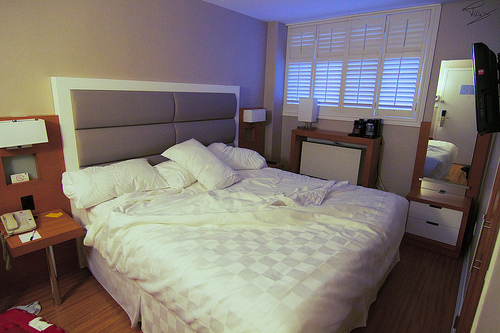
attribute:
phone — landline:
[1, 207, 37, 237]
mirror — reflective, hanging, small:
[424, 60, 477, 186]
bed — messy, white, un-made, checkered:
[86, 167, 406, 333]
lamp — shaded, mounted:
[1, 119, 49, 148]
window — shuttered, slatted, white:
[285, 8, 433, 116]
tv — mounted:
[472, 41, 497, 133]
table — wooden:
[288, 127, 383, 186]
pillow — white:
[162, 133, 243, 192]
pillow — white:
[206, 143, 267, 170]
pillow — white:
[155, 160, 197, 191]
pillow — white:
[63, 154, 168, 211]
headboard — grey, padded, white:
[51, 77, 240, 171]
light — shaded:
[243, 107, 267, 123]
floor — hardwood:
[356, 242, 461, 333]